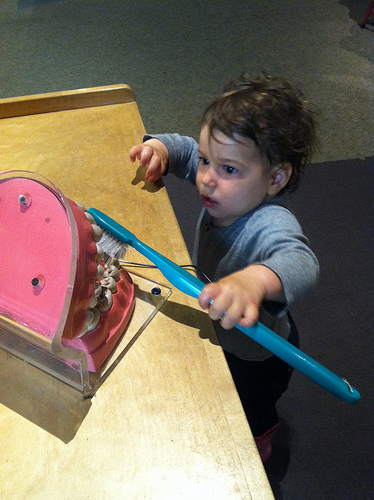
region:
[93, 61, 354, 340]
a small child holding a tooth brush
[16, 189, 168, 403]
a set of big teeth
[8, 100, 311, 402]
a child brushing teeth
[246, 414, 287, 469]
a pink shoe on foot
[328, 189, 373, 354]
a dark gray carpet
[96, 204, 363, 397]
a blue handle tooth brush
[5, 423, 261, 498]
a wooden table top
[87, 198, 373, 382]
a tooth brush in left hand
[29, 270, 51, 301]
bolts in the top of teeth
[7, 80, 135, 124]
a edge of a table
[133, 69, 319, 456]
a baby is standing at the table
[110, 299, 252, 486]
the table is tan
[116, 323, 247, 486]
the table is made of wood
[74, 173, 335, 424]
baby is holding a giant toothbrush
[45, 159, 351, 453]
the toothbrush is blue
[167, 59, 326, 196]
the baby`s hair is brown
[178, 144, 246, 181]
the eyes are open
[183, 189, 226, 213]
the lips are pink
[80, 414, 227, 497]
light is reflecting off the table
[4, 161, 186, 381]
the baby is brushing the teeth on the table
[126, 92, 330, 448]
little boy standing by a table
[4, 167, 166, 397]
large toy mouth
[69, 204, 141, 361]
pink gums on either side of the teeth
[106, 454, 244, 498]
light shining on the tabletop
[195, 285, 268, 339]
fingers curled around the blue handle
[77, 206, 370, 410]
large blue toothbrush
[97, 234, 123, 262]
bristles touching the teeth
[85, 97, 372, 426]
little kid holding a big toothbrush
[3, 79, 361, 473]
little kid brushing teeth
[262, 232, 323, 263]
wrinkles on the sleeve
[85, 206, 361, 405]
A large blue tooth brush.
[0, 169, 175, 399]
A large dental display.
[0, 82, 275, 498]
A light wooden table.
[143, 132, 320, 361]
A grey long sleeved shirt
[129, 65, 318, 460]
A small child.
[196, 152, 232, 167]
Eyes of a child.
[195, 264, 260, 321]
Right hand of child.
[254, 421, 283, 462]
Small boots on childs feet.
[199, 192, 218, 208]
Mouth of child.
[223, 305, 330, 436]
Pant's on a child.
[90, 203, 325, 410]
child holding a giant toothbrush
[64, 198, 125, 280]
child brushing giant teeth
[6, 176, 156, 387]
plastic teeth on a table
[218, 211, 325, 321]
child wearing a gray sweater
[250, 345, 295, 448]
child wearing black pants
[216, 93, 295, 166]
child with brown hair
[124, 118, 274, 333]
child reaching over table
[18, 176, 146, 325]
pink molding of teeth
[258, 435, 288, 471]
child wearing pink socks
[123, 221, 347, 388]
giant blue tooth brush